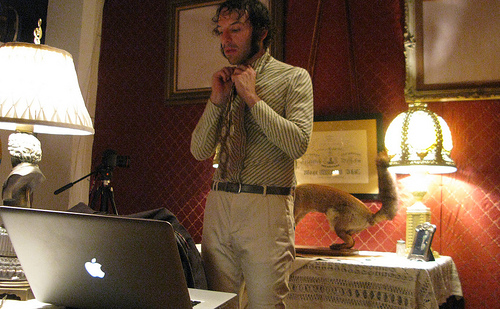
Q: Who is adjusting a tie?
A: A man.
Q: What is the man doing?
A: Tying tie.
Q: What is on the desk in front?
A: Laptop.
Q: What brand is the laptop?
A: Apple.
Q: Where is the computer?
A: Next to lamp.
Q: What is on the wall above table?
A: Frames.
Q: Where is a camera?
A: Left side of man.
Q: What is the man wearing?
A: Long sleeve shirt and khakis.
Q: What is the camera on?
A: Tripod.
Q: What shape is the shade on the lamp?
A: Dome shaped.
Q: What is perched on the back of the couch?
A: A stuffed animal.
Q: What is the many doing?
A: Tying a tie.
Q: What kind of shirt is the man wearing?
A: A dress shirt.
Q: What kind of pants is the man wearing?
A: Khaki's.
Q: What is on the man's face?
A: Side burns.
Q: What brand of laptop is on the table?
A: Apple.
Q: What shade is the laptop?
A: Silver.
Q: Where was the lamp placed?
A: On the table.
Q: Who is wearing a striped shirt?
A: Young man.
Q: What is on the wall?
A: Frame.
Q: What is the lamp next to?
A: A macbook.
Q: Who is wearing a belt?
A: The man.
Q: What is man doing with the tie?
A: Tying it.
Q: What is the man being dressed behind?
A: The computer.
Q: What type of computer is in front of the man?
A: Apple computer.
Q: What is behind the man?
A: A small stuffed animal.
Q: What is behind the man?
A: A tall, lit lamp.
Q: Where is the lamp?
A: To the left of the man.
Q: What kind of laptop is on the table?
A: Apple.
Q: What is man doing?
A: Tying his necktie.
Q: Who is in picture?
A: Man.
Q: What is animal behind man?
A: Mounted fox.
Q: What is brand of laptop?
A: Apple.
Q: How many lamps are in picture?
A: Two.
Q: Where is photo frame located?
A: On table behind man.